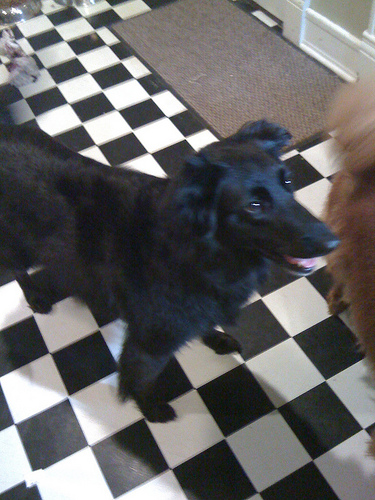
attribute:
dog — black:
[12, 65, 355, 440]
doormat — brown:
[111, 2, 371, 161]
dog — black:
[4, 107, 348, 434]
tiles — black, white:
[50, 50, 179, 163]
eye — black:
[282, 172, 298, 194]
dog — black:
[0, 102, 327, 426]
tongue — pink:
[279, 255, 323, 270]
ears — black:
[232, 114, 292, 152]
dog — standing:
[2, 134, 311, 376]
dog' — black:
[30, 55, 373, 446]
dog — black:
[30, 75, 365, 456]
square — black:
[106, 82, 168, 145]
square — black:
[231, 425, 310, 496]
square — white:
[290, 390, 352, 451]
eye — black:
[242, 198, 265, 213]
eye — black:
[281, 177, 291, 188]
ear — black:
[244, 113, 293, 154]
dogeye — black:
[281, 175, 291, 187]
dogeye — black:
[245, 196, 264, 211]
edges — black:
[110, 26, 181, 106]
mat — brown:
[113, 1, 347, 138]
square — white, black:
[143, 394, 217, 460]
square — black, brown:
[195, 360, 274, 438]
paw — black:
[206, 330, 244, 353]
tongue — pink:
[278, 249, 318, 271]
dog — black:
[8, 87, 340, 422]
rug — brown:
[70, 43, 317, 243]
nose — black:
[318, 234, 338, 251]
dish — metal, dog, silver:
[0, 0, 43, 27]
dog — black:
[31, 92, 354, 435]